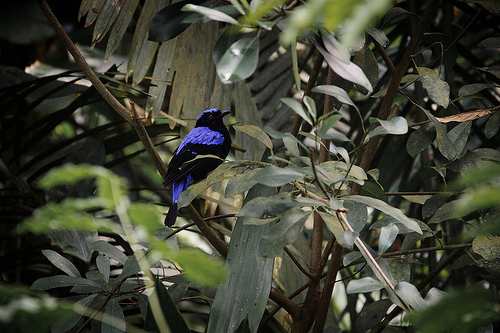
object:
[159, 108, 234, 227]
bird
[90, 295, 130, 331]
leaf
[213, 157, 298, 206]
leaf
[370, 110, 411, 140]
leaf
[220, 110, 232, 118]
beak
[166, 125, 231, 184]
body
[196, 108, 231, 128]
head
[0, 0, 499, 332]
background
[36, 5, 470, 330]
trees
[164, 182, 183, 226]
tail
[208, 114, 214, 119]
eye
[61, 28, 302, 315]
branch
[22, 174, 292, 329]
leaves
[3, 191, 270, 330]
foreground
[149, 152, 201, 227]
limb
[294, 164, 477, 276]
leaves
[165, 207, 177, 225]
feather